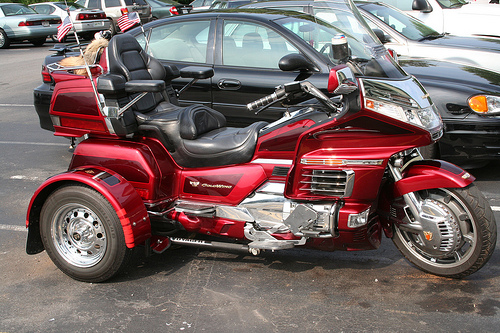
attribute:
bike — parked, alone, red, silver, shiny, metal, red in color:
[23, 36, 498, 284]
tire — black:
[417, 142, 436, 160]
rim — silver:
[50, 203, 108, 271]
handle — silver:
[248, 90, 285, 113]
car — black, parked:
[124, 6, 499, 171]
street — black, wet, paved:
[0, 43, 499, 332]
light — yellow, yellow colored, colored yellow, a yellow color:
[468, 94, 487, 116]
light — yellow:
[367, 101, 373, 109]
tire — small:
[385, 182, 496, 279]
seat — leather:
[104, 33, 269, 170]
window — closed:
[222, 20, 318, 73]